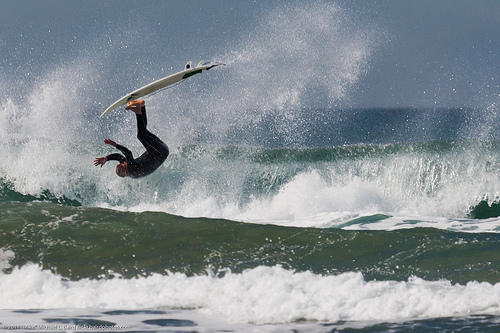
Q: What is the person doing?
A: Surfing.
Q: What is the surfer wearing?
A: A wetsuit.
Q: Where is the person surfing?
A: The ocean.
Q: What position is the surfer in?
A: Upside down.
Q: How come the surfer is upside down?
A: He wiped out.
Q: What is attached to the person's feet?
A: Surfboard.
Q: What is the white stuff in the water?
A: Seafoam.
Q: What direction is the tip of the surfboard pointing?
A: Down.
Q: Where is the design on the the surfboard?
A: The back.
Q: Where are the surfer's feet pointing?
A: Up.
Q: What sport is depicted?
A: Surfing.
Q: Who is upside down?
A: Surfer.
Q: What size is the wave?
A: Large.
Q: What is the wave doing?
A: Splashing.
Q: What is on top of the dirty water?
A: Suffer.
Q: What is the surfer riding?
A: Surfboard.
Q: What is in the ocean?
A: Waves.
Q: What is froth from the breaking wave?
A: Surfer.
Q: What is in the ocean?
A: Wave.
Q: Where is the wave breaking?
A: The ocean.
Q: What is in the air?
A: Surfboard.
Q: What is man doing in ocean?
A: Upside down.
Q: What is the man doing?
A: Surfing.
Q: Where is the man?
A: In the ocean.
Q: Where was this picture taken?
A: In the ocean.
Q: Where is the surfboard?
A: On the man's feet.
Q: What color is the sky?
A: Blue.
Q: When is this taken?
A: During the day.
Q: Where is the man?
A: In the water.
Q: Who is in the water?
A: The man.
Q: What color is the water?
A: Green.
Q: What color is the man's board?
A: White.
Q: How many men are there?
A: One.